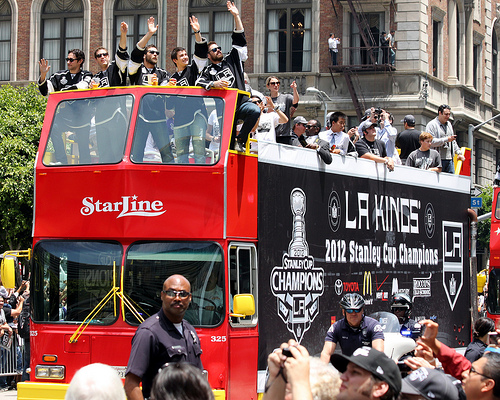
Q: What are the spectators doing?
A: Cheering for a team.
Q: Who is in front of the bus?
A: Police officer.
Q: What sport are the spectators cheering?
A: Hockey.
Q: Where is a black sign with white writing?
A: On the bus.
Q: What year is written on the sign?
A: 2012.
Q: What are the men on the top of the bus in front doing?
A: Waving.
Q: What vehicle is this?
A: Double decker bus.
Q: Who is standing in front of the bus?
A: Police officer.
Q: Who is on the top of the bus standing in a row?
A: Some men.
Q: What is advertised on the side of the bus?
A: LA Kings, 2012 Stanley Cup Champions.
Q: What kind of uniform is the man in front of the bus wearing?
A: Wearing a police uniform.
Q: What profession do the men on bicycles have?
A: Police officers.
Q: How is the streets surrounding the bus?
A: Busy with crowds of people.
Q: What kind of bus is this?
A: Double decker.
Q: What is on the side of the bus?
A: Advertisement of stanley cup.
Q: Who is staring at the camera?
A: A bald man.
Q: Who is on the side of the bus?
A: LA Kings Hockey Team.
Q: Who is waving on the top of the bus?
A: The hockey team.